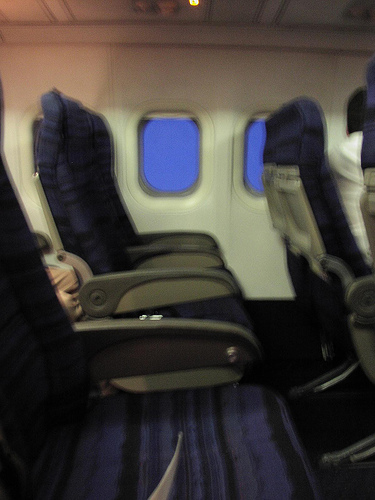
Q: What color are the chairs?
A: Black and blue.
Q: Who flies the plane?
A: Captain.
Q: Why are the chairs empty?
A: No ticket for the seats.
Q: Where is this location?
A: Airplane.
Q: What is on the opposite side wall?
A: Window.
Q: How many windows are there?
A: Two.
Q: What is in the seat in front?
A: A person.